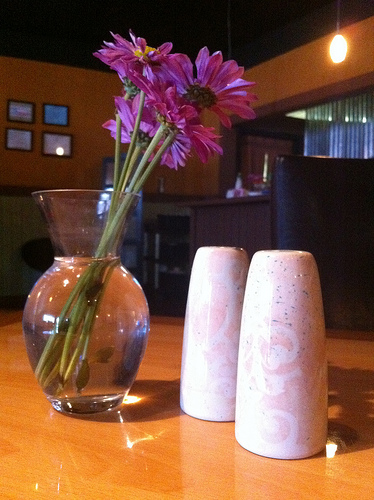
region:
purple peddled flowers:
[96, 23, 264, 178]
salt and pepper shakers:
[177, 235, 340, 472]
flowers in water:
[20, 24, 259, 418]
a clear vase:
[20, 171, 159, 424]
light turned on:
[322, 20, 364, 90]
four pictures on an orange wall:
[0, 86, 83, 175]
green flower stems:
[91, 116, 173, 372]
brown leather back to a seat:
[255, 116, 373, 331]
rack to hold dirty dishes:
[138, 203, 202, 306]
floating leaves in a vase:
[73, 331, 126, 405]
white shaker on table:
[248, 237, 353, 411]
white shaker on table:
[166, 245, 262, 378]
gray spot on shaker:
[266, 287, 314, 339]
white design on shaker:
[259, 321, 299, 373]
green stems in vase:
[66, 226, 135, 320]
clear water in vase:
[87, 266, 128, 380]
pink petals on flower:
[117, 110, 235, 148]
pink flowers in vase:
[93, 84, 248, 164]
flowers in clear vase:
[33, 162, 159, 254]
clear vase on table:
[44, 249, 173, 478]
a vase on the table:
[2, 139, 154, 441]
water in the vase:
[3, 232, 170, 424]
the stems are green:
[41, 154, 169, 383]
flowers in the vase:
[17, 8, 259, 310]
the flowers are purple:
[65, 10, 260, 186]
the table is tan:
[34, 419, 212, 492]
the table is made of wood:
[28, 412, 212, 492]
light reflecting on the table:
[92, 378, 166, 476]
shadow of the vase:
[96, 360, 184, 435]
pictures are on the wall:
[1, 82, 89, 178]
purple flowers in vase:
[36, 14, 263, 267]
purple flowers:
[90, 21, 263, 174]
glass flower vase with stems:
[17, 174, 159, 426]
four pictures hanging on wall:
[1, 92, 78, 167]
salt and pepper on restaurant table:
[171, 235, 364, 498]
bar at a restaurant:
[167, 151, 358, 244]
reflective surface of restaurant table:
[9, 414, 194, 496]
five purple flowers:
[86, 22, 243, 192]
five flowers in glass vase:
[29, 30, 263, 266]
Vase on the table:
[17, 171, 146, 420]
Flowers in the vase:
[90, 39, 242, 268]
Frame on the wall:
[36, 95, 71, 129]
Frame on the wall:
[3, 94, 37, 126]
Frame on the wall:
[33, 128, 78, 164]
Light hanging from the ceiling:
[324, 0, 358, 74]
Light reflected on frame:
[46, 147, 70, 159]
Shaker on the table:
[233, 247, 344, 461]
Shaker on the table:
[177, 240, 251, 432]